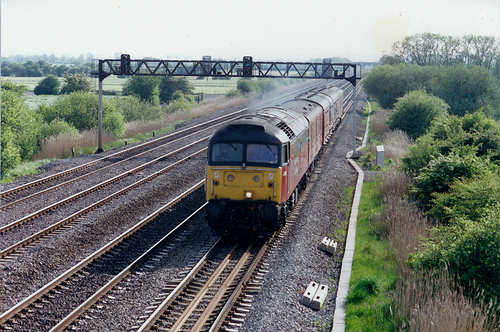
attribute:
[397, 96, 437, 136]
leaves — green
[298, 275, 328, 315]
ties — wooden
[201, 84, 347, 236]
train — black, red, yellow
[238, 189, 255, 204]
light — on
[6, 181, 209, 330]
track — brown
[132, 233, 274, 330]
track — brown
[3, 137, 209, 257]
track — brown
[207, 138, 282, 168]
windshield — black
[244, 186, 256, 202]
light — round, bright, on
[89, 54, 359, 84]
pole — black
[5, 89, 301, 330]
train tracks — metal , rusty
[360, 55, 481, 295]
bushes — green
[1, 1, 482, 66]
sky — light, clear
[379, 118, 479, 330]
straw — yellow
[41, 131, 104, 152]
straw — yellow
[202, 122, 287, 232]
front — yellow, black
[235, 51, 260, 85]
light — green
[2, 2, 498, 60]
sky — white, hazy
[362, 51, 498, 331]
bushes — green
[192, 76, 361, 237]
train — yellow, red